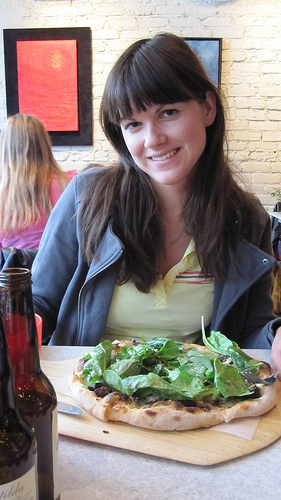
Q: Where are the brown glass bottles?
A: Bottom left corner.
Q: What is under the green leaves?
A: Pizza.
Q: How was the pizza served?
A: Wooden paddle.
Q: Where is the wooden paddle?
A: Under pizza.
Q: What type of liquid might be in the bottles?
A: Beer.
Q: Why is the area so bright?
A: Daytime sunlight.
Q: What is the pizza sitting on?
A: Formica table.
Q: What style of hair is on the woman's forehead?
A: Bangs.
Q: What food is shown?
A: Pizza.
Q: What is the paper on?
A: Wood cutting board.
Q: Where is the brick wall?
A: Behind woman in grey.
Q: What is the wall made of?
A: Bricks.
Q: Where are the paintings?
A: On brick wall.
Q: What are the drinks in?
A: Bottles.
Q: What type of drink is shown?
A: Beer.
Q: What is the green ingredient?
A: Spinach.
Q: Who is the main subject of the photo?
A: A woman.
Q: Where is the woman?
A: In a restaurant.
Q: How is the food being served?
A: On a board.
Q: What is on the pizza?
A: Spinach.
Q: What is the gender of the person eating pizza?
A: Female.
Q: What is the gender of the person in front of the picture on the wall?
A: Female.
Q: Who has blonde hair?
A: A woman.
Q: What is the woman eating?
A: A pizza.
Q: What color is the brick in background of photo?
A: Off white.